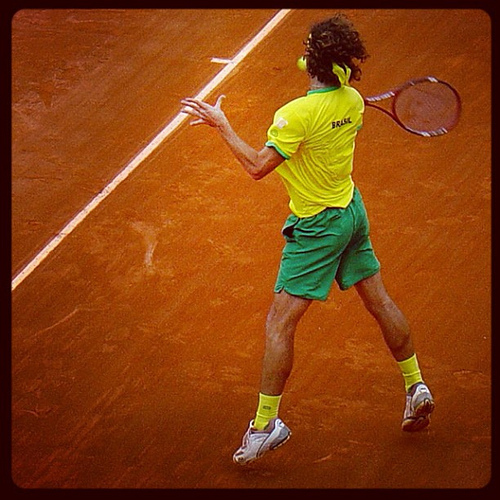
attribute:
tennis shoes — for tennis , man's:
[222, 352, 449, 461]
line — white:
[148, 123, 163, 159]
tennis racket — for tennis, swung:
[333, 66, 458, 146]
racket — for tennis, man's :
[337, 73, 477, 142]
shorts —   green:
[265, 191, 395, 301]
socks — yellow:
[393, 354, 428, 395]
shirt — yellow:
[251, 101, 455, 241]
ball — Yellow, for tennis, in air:
[295, 53, 312, 70]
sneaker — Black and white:
[232, 416, 290, 466]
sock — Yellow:
[252, 390, 277, 427]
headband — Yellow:
[330, 57, 360, 87]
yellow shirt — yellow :
[261, 87, 363, 219]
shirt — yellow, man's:
[266, 83, 365, 218]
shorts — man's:
[271, 204, 378, 294]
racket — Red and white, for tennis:
[371, 44, 466, 155]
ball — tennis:
[288, 47, 311, 75]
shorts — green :
[270, 187, 382, 303]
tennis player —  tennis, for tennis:
[176, 9, 436, 469]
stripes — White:
[416, 127, 448, 137]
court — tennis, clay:
[38, 55, 330, 299]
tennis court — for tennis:
[30, 92, 206, 242]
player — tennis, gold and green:
[181, 12, 435, 466]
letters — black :
[329, 119, 340, 133]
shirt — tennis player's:
[265, 89, 371, 219]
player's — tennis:
[184, 38, 483, 371]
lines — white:
[79, 184, 111, 212]